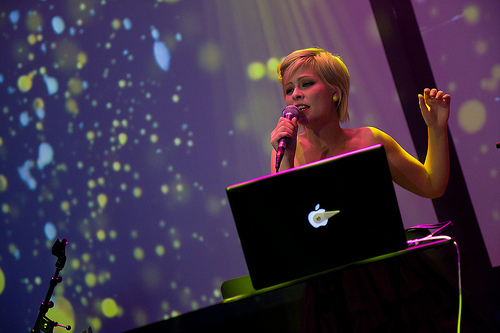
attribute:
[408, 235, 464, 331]
wire — white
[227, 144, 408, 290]
laptop — black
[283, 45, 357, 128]
hair — short, blonde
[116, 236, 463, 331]
black podium — long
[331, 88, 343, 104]
earring — pearl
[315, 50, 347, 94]
hair — blonde, straight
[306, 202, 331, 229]
apple logo — white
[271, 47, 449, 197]
woman — white, blonde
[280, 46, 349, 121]
hair — short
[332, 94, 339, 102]
earrings — light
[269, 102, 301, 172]
microphone — black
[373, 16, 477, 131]
pillar — large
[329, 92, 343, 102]
earing — round, light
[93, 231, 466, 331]
table — black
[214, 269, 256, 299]
chair — black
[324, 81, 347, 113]
earring — large 